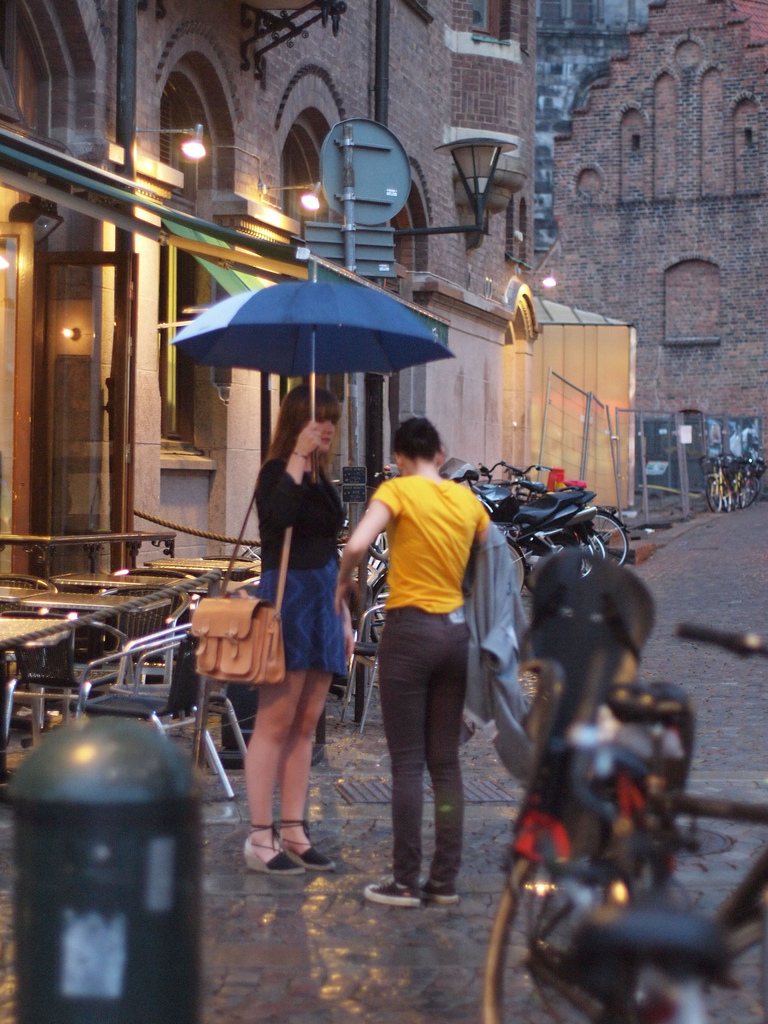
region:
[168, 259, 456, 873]
woman holding a blue umbrella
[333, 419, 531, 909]
person holding a gray coat in her hand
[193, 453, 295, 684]
a brown leather purse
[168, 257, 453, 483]
a blue umbrella with a silver top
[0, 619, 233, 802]
a silver chair sitting in front of a table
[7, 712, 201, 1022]
a green trash can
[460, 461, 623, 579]
parked bicycles under the rain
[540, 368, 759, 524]
a crooked metal fence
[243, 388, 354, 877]
woman wearing a black shirt and a blue skirt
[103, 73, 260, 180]
these are archways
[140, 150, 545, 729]
the people are standing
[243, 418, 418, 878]
the girl is under the umbrella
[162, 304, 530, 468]
the umbrella is blue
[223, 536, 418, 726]
the skirt is blue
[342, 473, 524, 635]
the shirt is yellow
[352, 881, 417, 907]
shoe on the foot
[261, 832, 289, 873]
shoe on the foot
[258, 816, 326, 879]
shoe on the foot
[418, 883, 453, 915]
shoe on the foot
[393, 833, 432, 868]
leg of the person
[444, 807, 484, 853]
leg of the person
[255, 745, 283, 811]
leg of the person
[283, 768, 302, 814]
leg of the person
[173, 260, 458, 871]
a woman holding a umbrella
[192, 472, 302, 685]
a tan shoulder bag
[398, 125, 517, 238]
a light on a black pole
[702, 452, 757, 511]
bike cycles parked by a fence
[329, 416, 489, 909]
a woman in a yellow shirt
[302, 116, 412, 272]
a sign on a gray post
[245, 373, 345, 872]
a woman wearing a blue dress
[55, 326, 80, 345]
a light on a brick wall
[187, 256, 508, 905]
a couple standing under a umbrella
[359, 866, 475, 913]
Person wearing shoes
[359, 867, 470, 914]
Person is wearing shoes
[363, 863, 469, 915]
Person wearing black and white shoes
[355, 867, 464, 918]
Person is wearing black and white shoes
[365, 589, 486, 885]
Person wearing pants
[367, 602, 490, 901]
Person is wearing pants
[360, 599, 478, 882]
Person wearing brown pants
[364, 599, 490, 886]
Person wearing dark brown pants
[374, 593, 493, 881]
Person is wearing brown pants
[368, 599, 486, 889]
Person is wearing dark brown pants